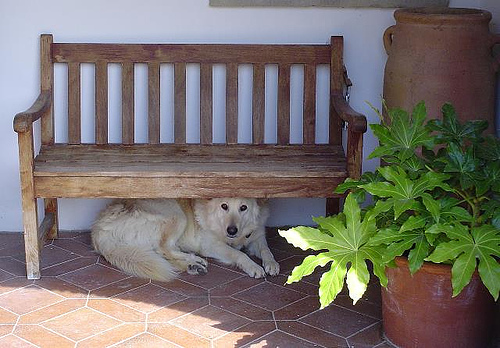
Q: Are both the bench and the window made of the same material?
A: Yes, both the bench and the window are made of wood.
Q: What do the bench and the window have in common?
A: The material, both the bench and the window are wooden.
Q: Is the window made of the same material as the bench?
A: Yes, both the window and the bench are made of wood.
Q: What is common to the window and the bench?
A: The material, both the window and the bench are wooden.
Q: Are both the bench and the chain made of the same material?
A: No, the bench is made of wood and the chain is made of metal.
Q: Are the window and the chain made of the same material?
A: No, the window is made of wood and the chain is made of metal.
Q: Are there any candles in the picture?
A: No, there are no candles.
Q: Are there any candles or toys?
A: No, there are no candles or toys.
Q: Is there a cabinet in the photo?
A: No, there are no cabinets.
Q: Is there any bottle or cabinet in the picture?
A: No, there are no cabinets or bottles.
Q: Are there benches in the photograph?
A: Yes, there is a bench.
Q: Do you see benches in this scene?
A: Yes, there is a bench.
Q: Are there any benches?
A: Yes, there is a bench.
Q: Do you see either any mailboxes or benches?
A: Yes, there is a bench.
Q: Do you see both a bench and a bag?
A: No, there is a bench but no bags.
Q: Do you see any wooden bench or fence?
A: Yes, there is a wood bench.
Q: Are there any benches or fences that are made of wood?
A: Yes, the bench is made of wood.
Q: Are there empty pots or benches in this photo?
A: Yes, there is an empty bench.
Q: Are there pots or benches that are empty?
A: Yes, the bench is empty.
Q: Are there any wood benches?
A: Yes, there is a wood bench.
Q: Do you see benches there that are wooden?
A: Yes, there is a bench that is wooden.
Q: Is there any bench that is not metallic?
A: Yes, there is a wooden bench.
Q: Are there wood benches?
A: Yes, there is a bench that is made of wood.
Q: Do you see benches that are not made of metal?
A: Yes, there is a bench that is made of wood.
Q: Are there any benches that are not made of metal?
A: Yes, there is a bench that is made of wood.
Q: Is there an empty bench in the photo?
A: Yes, there is an empty bench.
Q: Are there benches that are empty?
A: Yes, there is a bench that is empty.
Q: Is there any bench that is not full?
A: Yes, there is a empty bench.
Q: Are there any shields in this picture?
A: No, there are no shields.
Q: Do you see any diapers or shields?
A: No, there are no shields or diapers.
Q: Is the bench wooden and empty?
A: Yes, the bench is wooden and empty.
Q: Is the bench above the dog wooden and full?
A: No, the bench is wooden but empty.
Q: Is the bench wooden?
A: Yes, the bench is wooden.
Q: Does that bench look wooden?
A: Yes, the bench is wooden.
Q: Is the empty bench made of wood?
A: Yes, the bench is made of wood.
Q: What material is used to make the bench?
A: The bench is made of wood.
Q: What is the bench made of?
A: The bench is made of wood.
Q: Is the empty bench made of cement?
A: No, the bench is made of wood.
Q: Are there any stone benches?
A: No, there is a bench but it is made of wood.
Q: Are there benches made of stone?
A: No, there is a bench but it is made of wood.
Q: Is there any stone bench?
A: No, there is a bench but it is made of wood.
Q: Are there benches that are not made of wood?
A: No, there is a bench but it is made of wood.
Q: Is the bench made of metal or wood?
A: The bench is made of wood.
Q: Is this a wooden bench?
A: Yes, this is a wooden bench.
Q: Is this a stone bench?
A: No, this is a wooden bench.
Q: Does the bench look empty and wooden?
A: Yes, the bench is empty and wooden.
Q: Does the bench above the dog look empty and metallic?
A: No, the bench is empty but wooden.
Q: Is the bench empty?
A: Yes, the bench is empty.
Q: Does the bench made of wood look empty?
A: Yes, the bench is empty.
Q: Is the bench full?
A: No, the bench is empty.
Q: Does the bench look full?
A: No, the bench is empty.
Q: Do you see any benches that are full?
A: No, there is a bench but it is empty.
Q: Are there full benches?
A: No, there is a bench but it is empty.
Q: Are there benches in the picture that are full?
A: No, there is a bench but it is empty.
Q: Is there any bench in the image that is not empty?
A: No, there is a bench but it is empty.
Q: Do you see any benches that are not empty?
A: No, there is a bench but it is empty.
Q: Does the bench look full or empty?
A: The bench is empty.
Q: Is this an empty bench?
A: Yes, this is an empty bench.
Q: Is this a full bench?
A: No, this is an empty bench.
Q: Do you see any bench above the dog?
A: Yes, there is a bench above the dog.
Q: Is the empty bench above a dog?
A: Yes, the bench is above a dog.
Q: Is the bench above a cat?
A: No, the bench is above a dog.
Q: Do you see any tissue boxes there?
A: No, there are no tissue boxes.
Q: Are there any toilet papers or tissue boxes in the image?
A: No, there are no tissue boxes or toilet papers.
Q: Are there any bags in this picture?
A: No, there are no bags.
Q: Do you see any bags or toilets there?
A: No, there are no bags or toilets.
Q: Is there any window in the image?
A: Yes, there is a window.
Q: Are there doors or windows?
A: Yes, there is a window.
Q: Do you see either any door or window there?
A: Yes, there is a window.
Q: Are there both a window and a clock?
A: No, there is a window but no clocks.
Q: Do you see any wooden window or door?
A: Yes, there is a wood window.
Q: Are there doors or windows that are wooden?
A: Yes, the window is wooden.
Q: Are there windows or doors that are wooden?
A: Yes, the window is wooden.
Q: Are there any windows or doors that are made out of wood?
A: Yes, the window is made of wood.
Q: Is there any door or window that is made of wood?
A: Yes, the window is made of wood.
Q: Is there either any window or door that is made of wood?
A: Yes, the window is made of wood.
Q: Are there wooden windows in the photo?
A: Yes, there is a wood window.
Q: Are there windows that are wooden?
A: Yes, there is a window that is wooden.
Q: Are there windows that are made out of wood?
A: Yes, there is a window that is made of wood.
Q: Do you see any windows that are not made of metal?
A: Yes, there is a window that is made of wood.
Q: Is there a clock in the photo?
A: No, there are no clocks.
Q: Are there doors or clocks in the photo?
A: No, there are no clocks or doors.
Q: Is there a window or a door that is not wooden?
A: No, there is a window but it is wooden.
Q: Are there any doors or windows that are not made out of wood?
A: No, there is a window but it is made of wood.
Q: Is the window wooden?
A: Yes, the window is wooden.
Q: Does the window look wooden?
A: Yes, the window is wooden.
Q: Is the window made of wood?
A: Yes, the window is made of wood.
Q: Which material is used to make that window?
A: The window is made of wood.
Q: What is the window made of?
A: The window is made of wood.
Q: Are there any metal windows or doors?
A: No, there is a window but it is wooden.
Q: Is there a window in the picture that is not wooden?
A: No, there is a window but it is wooden.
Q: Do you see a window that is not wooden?
A: No, there is a window but it is wooden.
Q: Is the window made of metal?
A: No, the window is made of wood.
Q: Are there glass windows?
A: No, there is a window but it is made of wood.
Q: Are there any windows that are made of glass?
A: No, there is a window but it is made of wood.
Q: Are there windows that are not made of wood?
A: No, there is a window but it is made of wood.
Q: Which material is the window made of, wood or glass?
A: The window is made of wood.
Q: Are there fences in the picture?
A: No, there are no fences.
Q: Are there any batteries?
A: No, there are no batteries.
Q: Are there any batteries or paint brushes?
A: No, there are no batteries or paint brushes.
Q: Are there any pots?
A: Yes, there is a pot.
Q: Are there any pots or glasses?
A: Yes, there is a pot.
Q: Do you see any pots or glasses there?
A: Yes, there is a pot.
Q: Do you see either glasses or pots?
A: Yes, there is a pot.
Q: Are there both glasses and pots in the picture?
A: No, there is a pot but no glasses.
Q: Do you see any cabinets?
A: No, there are no cabinets.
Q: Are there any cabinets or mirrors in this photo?
A: No, there are no cabinets or mirrors.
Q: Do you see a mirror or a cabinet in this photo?
A: No, there are no cabinets or mirrors.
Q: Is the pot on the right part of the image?
A: Yes, the pot is on the right of the image.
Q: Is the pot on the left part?
A: No, the pot is on the right of the image.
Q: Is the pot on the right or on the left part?
A: The pot is on the right of the image.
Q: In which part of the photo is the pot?
A: The pot is on the right of the image.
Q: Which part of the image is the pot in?
A: The pot is on the right of the image.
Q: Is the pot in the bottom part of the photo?
A: Yes, the pot is in the bottom of the image.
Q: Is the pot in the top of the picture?
A: No, the pot is in the bottom of the image.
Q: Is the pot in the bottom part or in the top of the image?
A: The pot is in the bottom of the image.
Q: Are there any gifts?
A: No, there are no gifts.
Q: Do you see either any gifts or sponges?
A: No, there are no gifts or sponges.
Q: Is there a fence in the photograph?
A: No, there are no fences.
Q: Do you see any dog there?
A: Yes, there is a dog.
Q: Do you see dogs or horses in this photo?
A: Yes, there is a dog.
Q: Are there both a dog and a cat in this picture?
A: No, there is a dog but no cats.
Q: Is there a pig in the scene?
A: No, there are no pigs.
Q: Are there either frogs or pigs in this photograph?
A: No, there are no pigs or frogs.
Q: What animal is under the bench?
A: The dog is under the bench.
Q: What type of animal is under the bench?
A: The animal is a dog.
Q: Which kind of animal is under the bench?
A: The animal is a dog.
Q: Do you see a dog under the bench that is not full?
A: Yes, there is a dog under the bench.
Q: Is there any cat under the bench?
A: No, there is a dog under the bench.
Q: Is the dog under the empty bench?
A: Yes, the dog is under the bench.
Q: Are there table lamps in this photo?
A: No, there are no table lamps.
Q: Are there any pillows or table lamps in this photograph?
A: No, there are no table lamps or pillows.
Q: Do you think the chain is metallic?
A: Yes, the chain is metallic.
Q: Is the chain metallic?
A: Yes, the chain is metallic.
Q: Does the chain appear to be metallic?
A: Yes, the chain is metallic.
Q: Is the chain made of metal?
A: Yes, the chain is made of metal.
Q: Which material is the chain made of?
A: The chain is made of metal.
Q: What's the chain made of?
A: The chain is made of metal.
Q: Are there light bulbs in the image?
A: No, there are no light bulbs.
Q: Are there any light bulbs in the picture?
A: No, there are no light bulbs.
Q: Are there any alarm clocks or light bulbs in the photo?
A: No, there are no light bulbs or alarm clocks.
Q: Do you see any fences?
A: No, there are no fences.